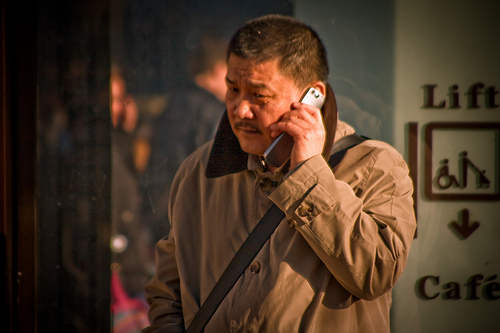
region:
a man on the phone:
[165, 15, 413, 331]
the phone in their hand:
[264, 77, 329, 169]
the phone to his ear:
[303, 77, 328, 114]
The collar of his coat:
[199, 114, 254, 189]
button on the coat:
[238, 257, 270, 277]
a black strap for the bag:
[173, 185, 285, 330]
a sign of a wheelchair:
[433, 151, 457, 205]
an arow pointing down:
[441, 202, 483, 239]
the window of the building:
[46, 74, 157, 326]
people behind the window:
[66, 29, 226, 264]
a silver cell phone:
[262, 84, 328, 171]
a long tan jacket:
[136, 80, 412, 330]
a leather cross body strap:
[175, 130, 372, 330]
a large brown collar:
[201, 80, 337, 178]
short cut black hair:
[222, 12, 327, 87]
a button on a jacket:
[246, 260, 259, 272]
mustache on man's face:
[230, 118, 260, 128]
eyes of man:
[220, 83, 273, 98]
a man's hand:
[267, 100, 324, 161]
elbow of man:
[336, 240, 400, 301]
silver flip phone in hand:
[265, 71, 339, 176]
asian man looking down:
[207, 7, 335, 175]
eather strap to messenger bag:
[199, 208, 289, 294]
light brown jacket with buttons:
[144, 132, 400, 321]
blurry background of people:
[114, 59, 222, 198]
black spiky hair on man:
[230, 18, 337, 81]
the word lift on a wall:
[404, 66, 498, 100]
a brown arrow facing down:
[439, 201, 492, 257]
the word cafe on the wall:
[417, 264, 494, 294]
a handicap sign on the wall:
[421, 127, 499, 204]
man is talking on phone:
[188, 8, 376, 193]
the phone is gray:
[257, 80, 352, 180]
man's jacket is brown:
[125, 81, 435, 317]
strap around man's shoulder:
[133, 114, 449, 331]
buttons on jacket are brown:
[233, 239, 280, 319]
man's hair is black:
[224, 16, 356, 129]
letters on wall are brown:
[375, 47, 497, 311]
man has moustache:
[226, 117, 261, 138]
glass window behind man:
[5, 2, 486, 311]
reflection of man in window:
[310, 46, 405, 154]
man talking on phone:
[123, 13, 427, 331]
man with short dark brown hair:
[144, 10, 429, 332]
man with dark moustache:
[138, 13, 416, 328]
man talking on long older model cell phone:
[146, 13, 428, 325]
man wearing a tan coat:
[131, 15, 443, 331]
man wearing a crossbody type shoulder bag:
[128, 13, 435, 329]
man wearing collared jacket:
[153, 10, 420, 332]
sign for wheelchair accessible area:
[401, 72, 498, 244]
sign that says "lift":
[418, 74, 498, 119]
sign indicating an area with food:
[409, 263, 496, 310]